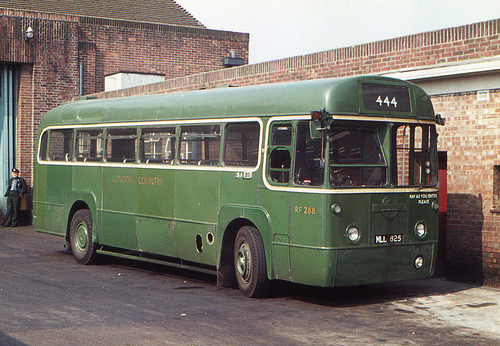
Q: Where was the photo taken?
A: It was taken at the road.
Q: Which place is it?
A: It is a road.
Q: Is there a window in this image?
A: Yes, there is a window.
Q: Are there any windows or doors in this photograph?
A: Yes, there is a window.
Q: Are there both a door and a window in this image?
A: Yes, there are both a window and a door.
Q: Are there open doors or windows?
A: Yes, there is an open window.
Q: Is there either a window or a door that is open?
A: Yes, the window is open.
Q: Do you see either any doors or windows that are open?
A: Yes, the window is open.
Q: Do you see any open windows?
A: Yes, there is an open window.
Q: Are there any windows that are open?
A: Yes, there is a window that is open.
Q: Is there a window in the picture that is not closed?
A: Yes, there is a open window.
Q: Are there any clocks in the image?
A: No, there are no clocks.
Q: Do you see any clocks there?
A: No, there are no clocks.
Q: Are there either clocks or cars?
A: No, there are no clocks or cars.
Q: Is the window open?
A: Yes, the window is open.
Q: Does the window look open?
A: Yes, the window is open.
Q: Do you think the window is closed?
A: No, the window is open.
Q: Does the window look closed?
A: No, the window is open.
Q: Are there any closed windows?
A: No, there is a window but it is open.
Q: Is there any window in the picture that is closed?
A: No, there is a window but it is open.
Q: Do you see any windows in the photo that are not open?
A: No, there is a window but it is open.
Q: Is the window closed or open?
A: The window is open.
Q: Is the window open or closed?
A: The window is open.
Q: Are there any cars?
A: No, there are no cars.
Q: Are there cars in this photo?
A: No, there are no cars.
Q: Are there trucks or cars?
A: No, there are no cars or trucks.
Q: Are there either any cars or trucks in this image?
A: No, there are no cars or trucks.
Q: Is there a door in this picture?
A: Yes, there is a door.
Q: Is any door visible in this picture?
A: Yes, there is a door.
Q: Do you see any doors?
A: Yes, there is a door.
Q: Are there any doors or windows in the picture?
A: Yes, there is a door.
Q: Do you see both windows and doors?
A: Yes, there are both a door and a window.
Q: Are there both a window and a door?
A: Yes, there are both a door and a window.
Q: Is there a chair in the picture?
A: No, there are no chairs.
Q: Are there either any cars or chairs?
A: No, there are no chairs or cars.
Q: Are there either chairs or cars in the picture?
A: No, there are no chairs or cars.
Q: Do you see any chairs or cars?
A: No, there are no chairs or cars.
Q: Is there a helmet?
A: No, there are no helmets.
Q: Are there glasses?
A: No, there are no glasses.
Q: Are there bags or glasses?
A: No, there are no glasses or bags.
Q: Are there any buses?
A: Yes, there is a bus.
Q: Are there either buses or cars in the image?
A: Yes, there is a bus.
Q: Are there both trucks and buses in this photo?
A: No, there is a bus but no trucks.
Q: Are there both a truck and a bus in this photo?
A: No, there is a bus but no trucks.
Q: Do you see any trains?
A: No, there are no trains.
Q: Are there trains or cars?
A: No, there are no trains or cars.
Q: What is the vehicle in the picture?
A: The vehicle is a bus.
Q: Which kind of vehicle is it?
A: The vehicle is a bus.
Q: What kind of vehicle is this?
A: That is a bus.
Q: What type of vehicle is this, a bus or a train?
A: That is a bus.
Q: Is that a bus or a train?
A: That is a bus.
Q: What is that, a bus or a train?
A: That is a bus.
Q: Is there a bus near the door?
A: Yes, there is a bus near the door.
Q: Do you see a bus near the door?
A: Yes, there is a bus near the door.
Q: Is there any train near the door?
A: No, there is a bus near the door.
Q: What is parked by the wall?
A: The bus is parked by the wall.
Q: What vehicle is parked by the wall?
A: The vehicle is a bus.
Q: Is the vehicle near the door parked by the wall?
A: Yes, the bus is parked by the wall.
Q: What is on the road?
A: The bus is on the road.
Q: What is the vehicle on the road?
A: The vehicle is a bus.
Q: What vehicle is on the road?
A: The vehicle is a bus.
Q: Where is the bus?
A: The bus is on the road.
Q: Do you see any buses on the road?
A: Yes, there is a bus on the road.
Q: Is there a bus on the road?
A: Yes, there is a bus on the road.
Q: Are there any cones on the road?
A: No, there is a bus on the road.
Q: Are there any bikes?
A: No, there are no bikes.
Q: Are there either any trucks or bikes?
A: No, there are no bikes or trucks.